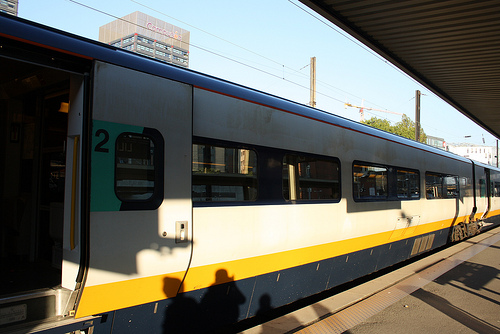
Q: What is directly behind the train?
A: Power lines.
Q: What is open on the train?
A: The door.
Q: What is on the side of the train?
A: Windows.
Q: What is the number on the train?
A: 2.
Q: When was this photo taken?
A: In the daytime.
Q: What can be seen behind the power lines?
A: Buildings.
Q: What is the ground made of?
A: Concrete.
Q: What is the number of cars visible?
A: Two.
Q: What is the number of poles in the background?
A: Two.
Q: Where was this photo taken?
A: By the train tracks.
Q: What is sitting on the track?
A: A train.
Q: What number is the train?
A: 2.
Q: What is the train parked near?
A: A roof.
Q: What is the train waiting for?
A: Passengers.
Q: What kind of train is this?
A: A passenger.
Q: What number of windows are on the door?
A: One.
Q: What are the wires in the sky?
A: Telephone wires.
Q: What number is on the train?
A: 2.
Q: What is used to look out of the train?
A: A window.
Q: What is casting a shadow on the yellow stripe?
A: Some people.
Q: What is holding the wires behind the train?
A: Telephone poles.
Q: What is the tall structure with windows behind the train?
A: A building.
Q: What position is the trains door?
A: Open.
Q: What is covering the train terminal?
A: An awning.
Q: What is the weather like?
A: Sunny.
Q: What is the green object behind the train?
A: Trees.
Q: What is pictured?
A: Train.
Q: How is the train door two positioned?
A: Open.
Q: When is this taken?
A: Daytime.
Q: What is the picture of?
A: A train.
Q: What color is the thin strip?
A: Yellow.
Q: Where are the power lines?
A: Above the train.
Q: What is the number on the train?
A: 2.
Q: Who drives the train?
A: A conductor.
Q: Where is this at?
A: A train station.